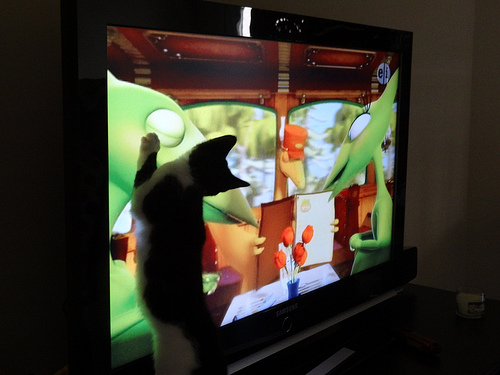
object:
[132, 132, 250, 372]
cat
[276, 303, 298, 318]
company name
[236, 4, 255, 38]
light reflection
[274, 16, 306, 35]
remote sensor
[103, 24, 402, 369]
image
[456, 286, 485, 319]
container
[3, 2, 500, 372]
paint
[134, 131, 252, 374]
fur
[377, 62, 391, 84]
channel logo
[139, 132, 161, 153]
paw of cat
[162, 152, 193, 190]
front neck of cat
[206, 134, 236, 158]
ears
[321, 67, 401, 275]
character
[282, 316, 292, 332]
power button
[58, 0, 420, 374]
tv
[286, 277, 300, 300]
vase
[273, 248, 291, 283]
tulips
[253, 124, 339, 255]
bird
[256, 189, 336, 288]
menu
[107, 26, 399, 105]
roof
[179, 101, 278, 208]
window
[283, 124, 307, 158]
hat